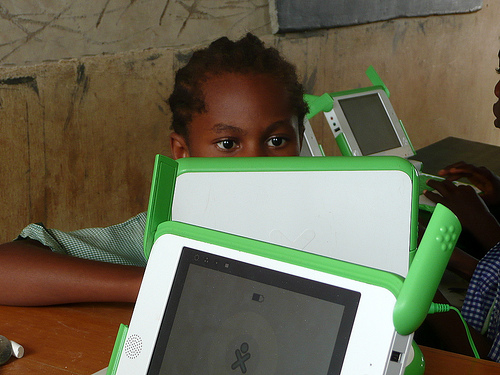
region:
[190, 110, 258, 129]
girl's bushy black eye brows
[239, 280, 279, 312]
small black spot on the tablet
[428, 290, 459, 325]
green electrical cord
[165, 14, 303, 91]
braids on child's head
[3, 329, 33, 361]
edge of white chalk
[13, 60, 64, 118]
small dent on brown wall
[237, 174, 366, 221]
white screen on board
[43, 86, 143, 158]
brown wall with marks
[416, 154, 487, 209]
child's hand on table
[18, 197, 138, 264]
green and white shirt sleeve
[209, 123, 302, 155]
brown eyes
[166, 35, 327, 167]
boy with short black hair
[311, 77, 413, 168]
green and white computer monitor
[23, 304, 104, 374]
brown table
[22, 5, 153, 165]
scratches on a brown cement wall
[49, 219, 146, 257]
green and white shirt sleeve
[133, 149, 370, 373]
two green and white computer monitors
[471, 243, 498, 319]
blue and white shirt sleeve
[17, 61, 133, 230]
tan cement wall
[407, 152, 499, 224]
hands typing on a keyboard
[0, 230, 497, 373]
Young kid's arm is on the table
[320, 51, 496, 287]
Young kid is typing on the computer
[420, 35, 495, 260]
A young kid is in the background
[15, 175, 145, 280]
Young kid is wearing a green shirt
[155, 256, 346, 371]
Computer screen is gray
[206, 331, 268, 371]
Computer screen has a "x" in the center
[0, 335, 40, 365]
White chalk is on the table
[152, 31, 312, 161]
Half of the young kids face is in view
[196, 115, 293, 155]
Young kid's eyes are brown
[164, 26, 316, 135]
Young kid's hair is in braids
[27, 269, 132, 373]
the table is wooden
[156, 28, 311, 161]
person with corn rows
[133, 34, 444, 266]
person looking at a monitor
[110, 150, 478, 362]
tablets in a green case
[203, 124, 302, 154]
young person'd black eyes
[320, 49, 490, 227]
boy typing on a lap top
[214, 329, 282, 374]
x on a lap top screen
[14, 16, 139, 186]
blackened wall of a school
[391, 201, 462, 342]
removeable portion of a laptop case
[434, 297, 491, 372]
green cord connected to a laptop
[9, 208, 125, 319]
arm in a green checkered shirt